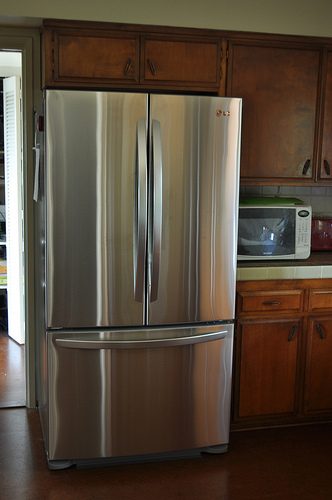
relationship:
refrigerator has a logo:
[33, 90, 246, 471] [215, 107, 232, 119]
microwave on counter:
[240, 198, 312, 262] [239, 258, 332, 284]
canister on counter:
[314, 216, 332, 255] [239, 258, 332, 284]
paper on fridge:
[31, 148, 43, 201] [33, 90, 246, 471]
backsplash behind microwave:
[241, 182, 332, 218] [240, 198, 312, 262]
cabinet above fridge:
[41, 19, 229, 96] [33, 90, 246, 471]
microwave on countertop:
[240, 198, 312, 262] [239, 258, 332, 284]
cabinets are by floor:
[233, 281, 331, 428] [3, 410, 332, 500]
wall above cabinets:
[2, 2, 332, 39] [233, 281, 331, 428]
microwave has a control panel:
[240, 198, 312, 262] [298, 217, 310, 255]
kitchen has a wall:
[0, 0, 331, 499] [2, 2, 332, 39]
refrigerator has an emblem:
[33, 90, 246, 471] [215, 107, 232, 119]